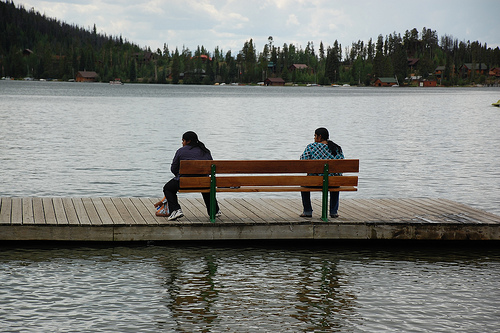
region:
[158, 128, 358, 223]
people sitting on a bench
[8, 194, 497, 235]
a wooden dock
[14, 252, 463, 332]
water around the dock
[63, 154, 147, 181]
small waves in the water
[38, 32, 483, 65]
trees on the hill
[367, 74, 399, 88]
a cabin next to the water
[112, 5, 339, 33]
clouds in the sky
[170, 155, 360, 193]
a wooden bench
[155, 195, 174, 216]
a bag next to the person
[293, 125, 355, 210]
a person in a blue shirt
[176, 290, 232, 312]
Part of the water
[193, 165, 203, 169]
Part of the bench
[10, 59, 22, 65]
Part of the trees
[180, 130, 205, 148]
The head of the woman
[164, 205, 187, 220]
The left foot of the woman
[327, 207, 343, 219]
The right foot of the person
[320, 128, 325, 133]
Part of the hair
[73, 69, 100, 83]
A house in distance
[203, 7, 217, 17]
Part of the cloud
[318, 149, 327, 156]
Part of the shirt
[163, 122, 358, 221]
a couple on a bench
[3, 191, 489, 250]
a pier on the water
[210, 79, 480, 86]
houses on the shore line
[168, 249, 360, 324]
a reflection in the water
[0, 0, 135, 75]
a tree cover hill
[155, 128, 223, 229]
a woman on a bench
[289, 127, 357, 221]
a man on a bench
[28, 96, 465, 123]
crystal clear water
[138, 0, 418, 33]
a blue and white sky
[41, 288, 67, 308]
water ripple in lake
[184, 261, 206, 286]
water ripple in lake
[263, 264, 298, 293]
water ripple in lake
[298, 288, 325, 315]
water ripple in lake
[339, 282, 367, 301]
water ripple in lake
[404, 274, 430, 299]
water ripple in lake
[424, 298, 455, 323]
water ripple in lake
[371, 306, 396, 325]
water ripple in lake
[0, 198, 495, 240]
A pier beneath the people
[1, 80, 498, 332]
A body of water around the pier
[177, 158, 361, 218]
A bench on the pier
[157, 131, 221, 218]
A person sitting on the bench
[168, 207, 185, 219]
A white shoe on the person's left foot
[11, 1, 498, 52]
The sky above the body of water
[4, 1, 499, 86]
Trees near the body of water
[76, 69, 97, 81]
A house by the body of water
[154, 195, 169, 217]
A purse on the pier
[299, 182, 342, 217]
The person is wearing pants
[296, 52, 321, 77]
green leaves on the tree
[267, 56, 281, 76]
green leaves on the tree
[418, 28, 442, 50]
green leaves on the tree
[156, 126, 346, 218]
two people sitting on a bench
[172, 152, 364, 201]
a brown wooden bench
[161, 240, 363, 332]
a shadow in the water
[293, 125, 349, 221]
man wearing a checked shirt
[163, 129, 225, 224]
a man wearing white shoes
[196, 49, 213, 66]
house with red roof on horizon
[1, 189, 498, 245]
pier in the water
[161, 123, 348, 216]
two men with long hair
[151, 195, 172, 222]
stripped bag sitting on the pier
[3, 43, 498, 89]
row of houses on the shore